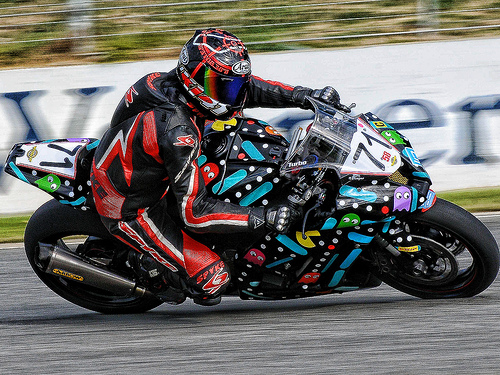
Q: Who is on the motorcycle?
A: The man.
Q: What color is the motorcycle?
A: Black, white, and blue.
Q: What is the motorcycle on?
A: Pavement.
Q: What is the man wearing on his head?
A: A helmet.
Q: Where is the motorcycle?
A: On the pavement.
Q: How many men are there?
A: One.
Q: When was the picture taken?
A: Daytime.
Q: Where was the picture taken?
A: On a racetrack.